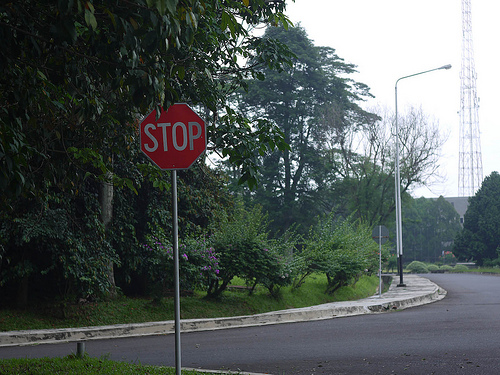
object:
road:
[273, 272, 496, 374]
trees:
[0, 46, 66, 205]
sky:
[320, 7, 451, 45]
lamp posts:
[394, 78, 404, 284]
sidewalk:
[303, 300, 372, 319]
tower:
[457, 9, 484, 197]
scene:
[323, 113, 338, 124]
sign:
[139, 103, 207, 170]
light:
[394, 148, 429, 276]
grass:
[98, 305, 137, 323]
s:
[138, 121, 160, 153]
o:
[171, 121, 188, 152]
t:
[156, 123, 171, 152]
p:
[188, 121, 203, 150]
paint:
[396, 257, 399, 275]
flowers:
[215, 270, 220, 274]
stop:
[143, 121, 201, 152]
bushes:
[203, 200, 279, 300]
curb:
[222, 320, 251, 330]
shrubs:
[134, 229, 221, 304]